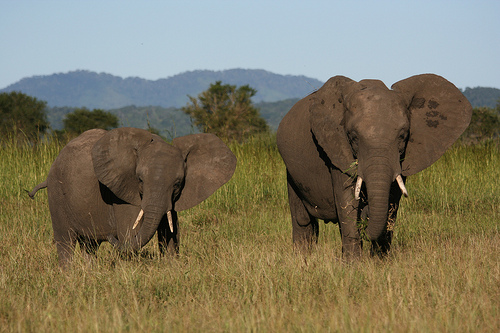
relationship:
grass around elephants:
[1, 130, 500, 332] [63, 88, 496, 250]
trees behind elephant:
[5, 87, 499, 159] [267, 56, 477, 270]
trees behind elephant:
[5, 87, 499, 159] [21, 124, 239, 265]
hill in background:
[0, 68, 499, 146] [53, 24, 297, 128]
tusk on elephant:
[394, 173, 409, 198] [287, 75, 495, 255]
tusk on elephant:
[353, 176, 363, 201] [287, 75, 495, 255]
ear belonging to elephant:
[309, 75, 358, 177] [236, 74, 474, 246]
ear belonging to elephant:
[391, 72, 473, 175] [236, 74, 474, 246]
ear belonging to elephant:
[92, 124, 144, 208] [275, 71, 472, 263]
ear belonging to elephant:
[309, 75, 358, 177] [275, 71, 472, 263]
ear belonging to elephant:
[309, 75, 358, 177] [254, 52, 444, 290]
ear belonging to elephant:
[391, 72, 473, 175] [254, 52, 444, 290]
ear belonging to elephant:
[92, 124, 144, 208] [21, 124, 239, 265]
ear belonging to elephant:
[173, 133, 237, 210] [21, 124, 239, 265]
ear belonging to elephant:
[391, 72, 473, 175] [263, 53, 464, 285]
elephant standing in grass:
[21, 124, 239, 265] [4, 265, 499, 331]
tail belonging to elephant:
[22, 179, 48, 200] [21, 124, 239, 265]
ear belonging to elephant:
[309, 75, 358, 177] [267, 56, 477, 270]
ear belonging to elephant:
[391, 72, 473, 175] [275, 71, 472, 263]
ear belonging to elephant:
[92, 125, 144, 212] [21, 124, 239, 265]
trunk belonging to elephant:
[356, 145, 408, 244] [267, 70, 475, 253]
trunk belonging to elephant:
[121, 186, 172, 261] [42, 124, 234, 249]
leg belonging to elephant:
[52, 202, 77, 267] [21, 124, 239, 265]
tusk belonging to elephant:
[352, 176, 363, 202] [279, 68, 477, 247]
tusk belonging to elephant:
[394, 173, 409, 198] [279, 68, 477, 247]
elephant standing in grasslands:
[275, 71, 472, 263] [3, 127, 493, 328]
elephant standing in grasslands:
[21, 124, 239, 265] [1, 91, 497, 331]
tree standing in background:
[183, 47, 321, 174] [1, 67, 483, 149]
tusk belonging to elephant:
[353, 176, 363, 201] [275, 71, 472, 263]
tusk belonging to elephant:
[131, 209, 145, 232] [21, 124, 239, 265]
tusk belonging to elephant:
[164, 206, 174, 235] [21, 124, 239, 265]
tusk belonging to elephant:
[394, 173, 409, 199] [275, 71, 472, 263]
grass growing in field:
[1, 130, 484, 331] [2, 125, 483, 331]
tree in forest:
[180, 78, 270, 142] [11, 95, 269, 139]